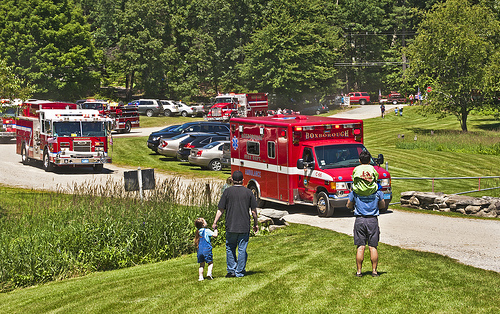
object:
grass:
[0, 99, 499, 314]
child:
[195, 214, 218, 282]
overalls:
[195, 226, 215, 263]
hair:
[359, 152, 371, 164]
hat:
[229, 170, 246, 179]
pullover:
[217, 182, 257, 234]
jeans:
[223, 232, 248, 277]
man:
[350, 184, 388, 275]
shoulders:
[349, 188, 383, 198]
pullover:
[348, 187, 382, 216]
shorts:
[350, 215, 380, 247]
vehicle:
[226, 107, 382, 218]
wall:
[400, 192, 500, 221]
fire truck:
[11, 96, 117, 173]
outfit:
[194, 226, 211, 267]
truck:
[384, 90, 406, 103]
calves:
[356, 247, 365, 265]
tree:
[382, 0, 499, 134]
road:
[0, 142, 499, 273]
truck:
[11, 97, 110, 172]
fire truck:
[78, 102, 143, 132]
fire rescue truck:
[10, 101, 113, 170]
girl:
[351, 149, 375, 196]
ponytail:
[360, 147, 367, 159]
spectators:
[209, 169, 258, 277]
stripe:
[10, 126, 30, 140]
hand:
[211, 224, 221, 231]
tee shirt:
[347, 188, 381, 216]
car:
[188, 141, 235, 168]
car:
[177, 132, 234, 159]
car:
[158, 132, 229, 157]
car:
[146, 121, 230, 150]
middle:
[0, 75, 498, 202]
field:
[0, 82, 498, 314]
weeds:
[0, 181, 269, 294]